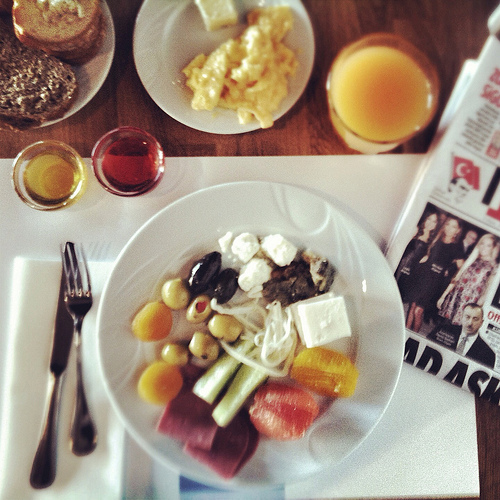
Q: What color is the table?
A: Brown.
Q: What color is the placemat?
A: White.